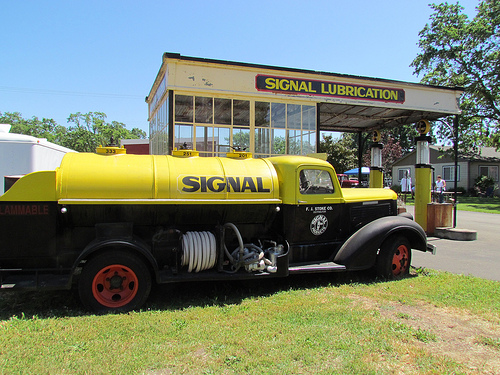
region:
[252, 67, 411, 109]
sign indicating signal lubrication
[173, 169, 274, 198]
logo for signal lubrication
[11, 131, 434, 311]
vintage oil truck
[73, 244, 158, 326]
truck tire with red rim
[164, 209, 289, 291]
oil delivery system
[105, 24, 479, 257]
lubrication garage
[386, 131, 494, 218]
wood house with aluminum siding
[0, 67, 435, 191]
row of green trees against a blue sky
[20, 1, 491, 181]
blue sky with no clouds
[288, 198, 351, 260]
corporate logo for the signal corporation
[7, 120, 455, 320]
black truck with yellow top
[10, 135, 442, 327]
truck with red rims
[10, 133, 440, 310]
truck with hose on side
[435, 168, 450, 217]
woman wearing white shirt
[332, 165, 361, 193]
red pick up truck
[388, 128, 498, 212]
brown single story house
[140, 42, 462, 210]
store with sign on top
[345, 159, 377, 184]
blue tent next to house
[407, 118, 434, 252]
yellow pole with ball on top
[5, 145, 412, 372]
truck parked on grass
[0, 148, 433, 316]
an old truck with a tank on it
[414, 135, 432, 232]
an antique gas pump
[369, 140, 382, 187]
a visible gas pump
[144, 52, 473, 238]
a restored gas station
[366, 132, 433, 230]
two yellow and black visible pumps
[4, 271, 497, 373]
a patch of grass by the truck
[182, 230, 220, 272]
a reel of white hose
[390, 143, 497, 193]
a house across the road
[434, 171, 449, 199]
a woman standing at a table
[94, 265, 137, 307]
a red rear wheel on the truck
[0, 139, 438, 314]
a yellow and black truck parked in the grass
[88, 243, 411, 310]
red rims on the tires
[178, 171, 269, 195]
a sign that says Signal on the side of the truck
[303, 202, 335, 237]
a white logo on the door of the truck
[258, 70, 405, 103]
a sign that says Signal Lubrication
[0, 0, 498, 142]
a clear blue sky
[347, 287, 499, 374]
a worn out patch in the grass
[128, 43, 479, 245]
a very small gas station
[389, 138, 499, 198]
a house on the other side of the street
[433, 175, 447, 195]
a person standing outside of the house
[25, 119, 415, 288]
black and white truck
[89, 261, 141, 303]
red hubcap on wheels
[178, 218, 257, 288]
white hose on truck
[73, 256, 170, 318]
black wheels on truck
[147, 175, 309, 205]
black company name on truck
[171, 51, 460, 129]
black and yellow sign on building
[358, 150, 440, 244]
yellow pylons near truck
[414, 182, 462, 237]
brown trash bin near truck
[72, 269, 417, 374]
green and brown ground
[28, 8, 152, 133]
blue and clear sky